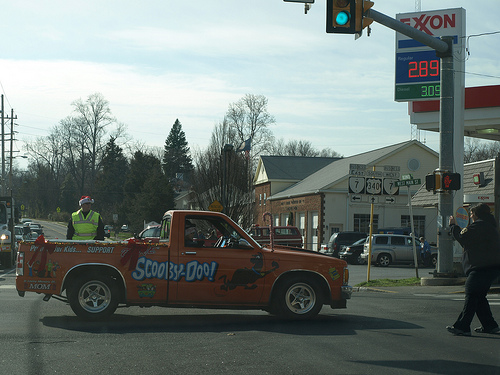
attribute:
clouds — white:
[5, 57, 219, 132]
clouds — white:
[108, 15, 275, 55]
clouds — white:
[272, 90, 369, 122]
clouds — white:
[307, 58, 394, 90]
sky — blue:
[3, 3, 488, 146]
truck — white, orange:
[14, 208, 350, 318]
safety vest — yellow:
[68, 206, 102, 241]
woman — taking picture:
[447, 203, 498, 335]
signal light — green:
[322, 1, 379, 41]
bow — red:
[24, 247, 52, 273]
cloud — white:
[1, 55, 344, 124]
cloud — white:
[261, 116, 385, 135]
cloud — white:
[94, 20, 385, 59]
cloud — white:
[36, 27, 66, 46]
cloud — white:
[362, 103, 409, 113]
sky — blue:
[2, 1, 483, 171]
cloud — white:
[106, 21, 388, 55]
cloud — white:
[288, 88, 394, 102]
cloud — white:
[2, 59, 351, 117]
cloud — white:
[22, 20, 71, 41]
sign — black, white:
[345, 160, 368, 203]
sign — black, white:
[363, 167, 383, 204]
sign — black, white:
[380, 162, 402, 202]